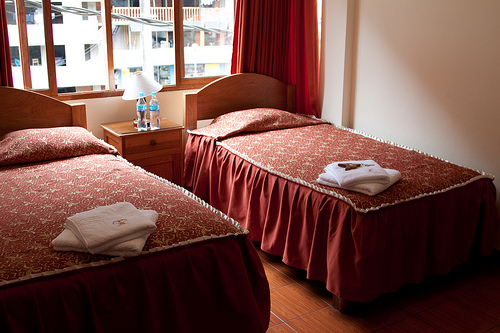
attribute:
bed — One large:
[182, 75, 498, 311]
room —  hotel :
[2, 5, 499, 330]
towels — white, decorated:
[310, 157, 401, 197]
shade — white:
[122, 72, 162, 104]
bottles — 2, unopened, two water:
[137, 97, 163, 131]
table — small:
[110, 120, 198, 188]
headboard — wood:
[187, 73, 309, 116]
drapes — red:
[233, 2, 319, 113]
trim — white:
[223, 145, 312, 204]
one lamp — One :
[123, 70, 163, 131]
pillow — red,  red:
[218, 109, 315, 133]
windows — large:
[6, 6, 239, 87]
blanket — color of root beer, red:
[191, 110, 500, 262]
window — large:
[109, 2, 184, 90]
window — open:
[5, 2, 85, 100]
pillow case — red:
[3, 126, 121, 169]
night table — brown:
[106, 124, 186, 171]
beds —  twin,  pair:
[20, 81, 484, 300]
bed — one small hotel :
[12, 92, 271, 319]